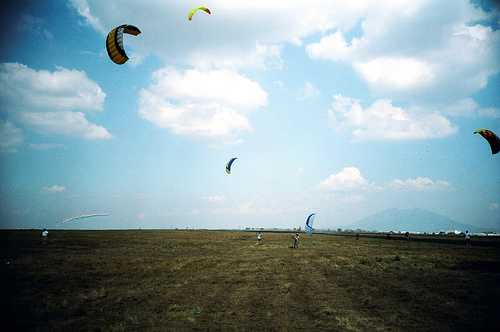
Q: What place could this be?
A: It is a field.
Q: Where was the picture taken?
A: It was taken at the field.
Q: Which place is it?
A: It is a field.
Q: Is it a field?
A: Yes, it is a field.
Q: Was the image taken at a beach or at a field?
A: It was taken at a field.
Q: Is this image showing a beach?
A: No, the picture is showing a field.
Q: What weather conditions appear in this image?
A: It is cloudy.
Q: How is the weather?
A: It is cloudy.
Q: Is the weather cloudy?
A: Yes, it is cloudy.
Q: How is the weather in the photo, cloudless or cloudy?
A: It is cloudy.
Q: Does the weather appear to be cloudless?
A: No, it is cloudy.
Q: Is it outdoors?
A: Yes, it is outdoors.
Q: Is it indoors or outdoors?
A: It is outdoors.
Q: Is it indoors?
A: No, it is outdoors.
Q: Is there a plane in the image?
A: No, there are no airplanes.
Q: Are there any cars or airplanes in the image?
A: No, there are no airplanes or cars.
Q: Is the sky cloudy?
A: Yes, the sky is cloudy.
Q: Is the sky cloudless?
A: No, the sky is cloudy.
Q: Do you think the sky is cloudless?
A: No, the sky is cloudy.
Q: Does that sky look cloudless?
A: No, the sky is cloudy.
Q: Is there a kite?
A: Yes, there is a kite.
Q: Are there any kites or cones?
A: Yes, there is a kite.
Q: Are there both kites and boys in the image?
A: No, there is a kite but no boys.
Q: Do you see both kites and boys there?
A: No, there is a kite but no boys.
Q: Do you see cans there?
A: No, there are no cans.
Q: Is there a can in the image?
A: No, there are no cans.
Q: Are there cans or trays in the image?
A: No, there are no cans or trays.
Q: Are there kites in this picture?
A: Yes, there is a kite.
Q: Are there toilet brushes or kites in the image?
A: Yes, there is a kite.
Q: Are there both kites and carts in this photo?
A: No, there is a kite but no carts.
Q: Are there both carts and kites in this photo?
A: No, there is a kite but no carts.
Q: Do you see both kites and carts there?
A: No, there is a kite but no carts.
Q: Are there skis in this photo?
A: No, there are no skis.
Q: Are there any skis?
A: No, there are no skis.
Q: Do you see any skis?
A: No, there are no skis.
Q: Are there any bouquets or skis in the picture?
A: No, there are no skis or bouquets.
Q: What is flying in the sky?
A: The kite is flying in the sky.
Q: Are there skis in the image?
A: No, there are no skis.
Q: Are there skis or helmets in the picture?
A: No, there are no skis or helmets.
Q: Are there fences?
A: No, there are no fences.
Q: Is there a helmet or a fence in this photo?
A: No, there are no fences or helmets.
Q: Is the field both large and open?
A: Yes, the field is large and open.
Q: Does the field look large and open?
A: Yes, the field is large and open.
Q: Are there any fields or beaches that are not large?
A: No, there is a field but it is large.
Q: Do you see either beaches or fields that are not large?
A: No, there is a field but it is large.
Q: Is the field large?
A: Yes, the field is large.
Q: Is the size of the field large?
A: Yes, the field is large.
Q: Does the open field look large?
A: Yes, the field is large.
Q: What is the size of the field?
A: The field is large.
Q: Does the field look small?
A: No, the field is large.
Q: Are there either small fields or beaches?
A: No, there is a field but it is large.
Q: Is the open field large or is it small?
A: The field is large.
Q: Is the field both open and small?
A: No, the field is open but large.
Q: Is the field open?
A: Yes, the field is open.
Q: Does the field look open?
A: Yes, the field is open.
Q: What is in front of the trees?
A: The field is in front of the trees.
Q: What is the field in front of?
A: The field is in front of the trees.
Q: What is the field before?
A: The field is in front of the trees.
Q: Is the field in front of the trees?
A: Yes, the field is in front of the trees.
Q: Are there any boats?
A: No, there are no boats.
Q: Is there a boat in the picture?
A: No, there are no boats.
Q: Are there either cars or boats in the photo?
A: No, there are no boats or cars.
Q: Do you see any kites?
A: Yes, there is a kite.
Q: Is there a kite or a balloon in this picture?
A: Yes, there is a kite.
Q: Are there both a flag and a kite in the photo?
A: No, there is a kite but no flags.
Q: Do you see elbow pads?
A: No, there are no elbow pads.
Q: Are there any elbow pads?
A: No, there are no elbow pads.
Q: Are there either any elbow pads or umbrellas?
A: No, there are no elbow pads or umbrellas.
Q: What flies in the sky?
A: The kite flies in the sky.